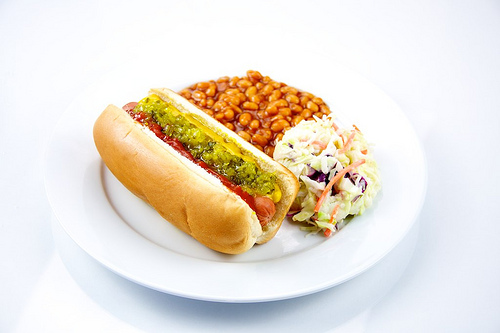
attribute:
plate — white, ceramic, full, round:
[57, 32, 429, 303]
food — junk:
[93, 70, 377, 255]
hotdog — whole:
[92, 85, 299, 255]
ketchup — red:
[134, 112, 255, 207]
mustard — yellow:
[151, 95, 259, 166]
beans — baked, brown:
[179, 69, 331, 158]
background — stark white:
[1, 1, 500, 330]